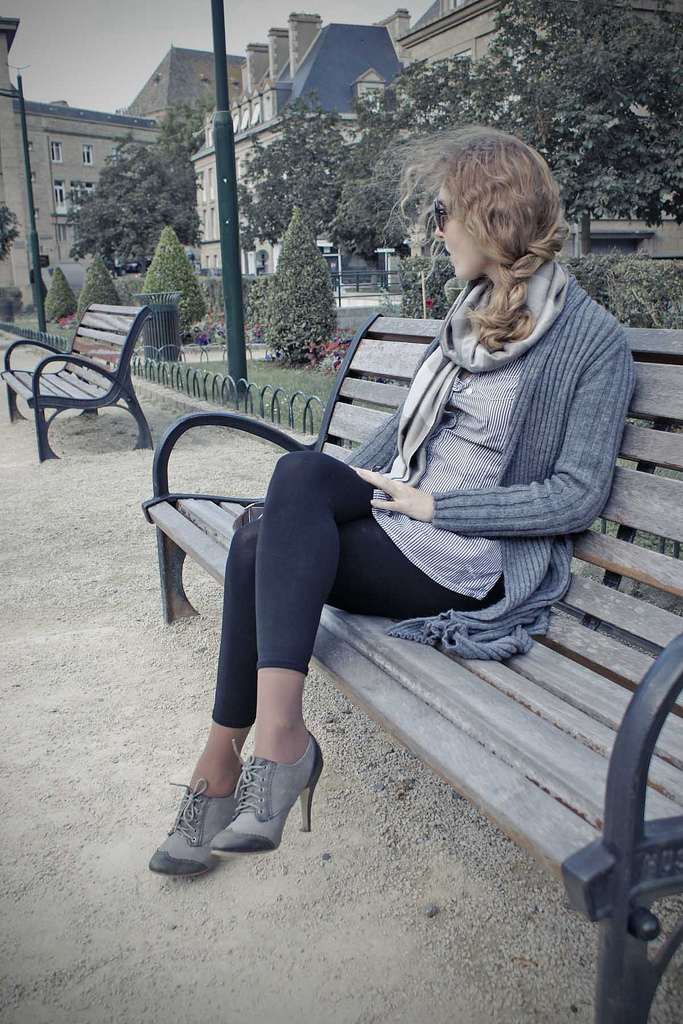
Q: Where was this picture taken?
A: On a park bench.